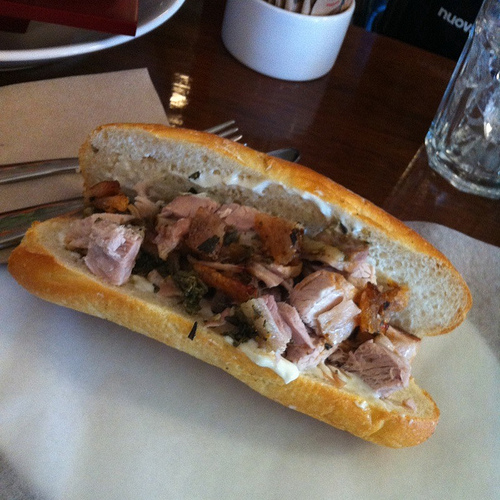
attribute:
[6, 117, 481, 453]
bread — split open, italian, white, golden brown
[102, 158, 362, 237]
cream — white, creamy, mayonnaise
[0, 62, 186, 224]
cloth — brown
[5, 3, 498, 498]
table — dark, dark brown, brown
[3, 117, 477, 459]
sandwich — herbed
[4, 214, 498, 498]
napkin — white, brown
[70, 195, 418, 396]
meat — spiced, pork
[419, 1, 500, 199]
glass — clear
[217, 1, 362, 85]
condiment dish — ceramic, white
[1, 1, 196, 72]
plate — white